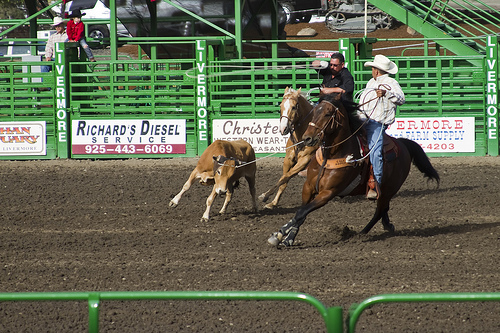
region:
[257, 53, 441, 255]
Two men on horses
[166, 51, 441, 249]
Men pulling a bull with a rope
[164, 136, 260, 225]
Brown and white bull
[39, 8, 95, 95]
Man and a boy in cowboy hats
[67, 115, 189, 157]
Rectangular white advertisement sign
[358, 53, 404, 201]
Man wearing a white cowboy hat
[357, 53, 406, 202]
Man wearing a white shirt and blue jeans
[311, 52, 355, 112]
Man wearing sunglasses and a black shirt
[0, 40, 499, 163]
Green metal fence and gates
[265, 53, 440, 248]
Man riding a horse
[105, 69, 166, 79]
green paint on the fence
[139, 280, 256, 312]
top of green railing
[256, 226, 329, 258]
black foot on horse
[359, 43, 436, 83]
beautiful white cowboy hat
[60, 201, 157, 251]
black dirt on the ground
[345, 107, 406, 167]
man wearing blue jeans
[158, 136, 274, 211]
small brown calf in the field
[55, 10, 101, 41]
boy wearing red shirt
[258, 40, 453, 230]
two men riding horses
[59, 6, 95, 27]
young boy wearing black hat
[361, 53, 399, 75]
white cowboy hat being worn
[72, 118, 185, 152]
sign for Richards Diesel Service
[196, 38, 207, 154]
green pole with white letters saying Livermore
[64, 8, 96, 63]
young cowboy with red shirt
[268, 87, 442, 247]
dark brown horse with black markings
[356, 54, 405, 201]
cowboy riding a horse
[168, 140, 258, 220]
cattle being roped by cowboy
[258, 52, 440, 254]
two men on horses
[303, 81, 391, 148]
reigns on dark colored horse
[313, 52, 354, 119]
man in black shirt on horse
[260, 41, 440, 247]
Two men riding horses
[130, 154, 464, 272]
They are riding on dirt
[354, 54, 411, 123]
This man is wearing a cowboy hat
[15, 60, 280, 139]
The metal fence is green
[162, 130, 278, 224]
This bull is being pulled by a man on a horse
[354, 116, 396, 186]
He is wearing blue jeans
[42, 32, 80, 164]
The green posts say Livermore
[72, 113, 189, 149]
An ad for Richard's Diesel Service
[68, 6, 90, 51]
A young boy in a black cowboy hat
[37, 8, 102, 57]
The man is holding the young boy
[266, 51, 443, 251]
A person riding the horse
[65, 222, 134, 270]
Part of the mud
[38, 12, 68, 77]
A person sitting in distance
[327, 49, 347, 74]
The head of the person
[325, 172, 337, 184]
Part of the hourse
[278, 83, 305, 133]
The head of the horse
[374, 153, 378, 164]
Part of the pants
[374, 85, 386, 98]
The left hand of the person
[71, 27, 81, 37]
Part of the red shirt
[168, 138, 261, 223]
A small brown cow.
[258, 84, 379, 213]
A lighter brown horse.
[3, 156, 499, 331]
Brown dirt area in between green fencing.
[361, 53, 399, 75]
A white cowboy hat.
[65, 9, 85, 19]
Black cowboy hat on a red shirt boy.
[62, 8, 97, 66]
Boy in a red shirt with a black hat on.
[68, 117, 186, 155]
Rectangle sign that has a 443 on the bottom.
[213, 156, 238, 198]
Head of a small cow.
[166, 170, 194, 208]
Cows leg off the ground.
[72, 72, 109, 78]
railing is bright green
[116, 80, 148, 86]
railing is bright green